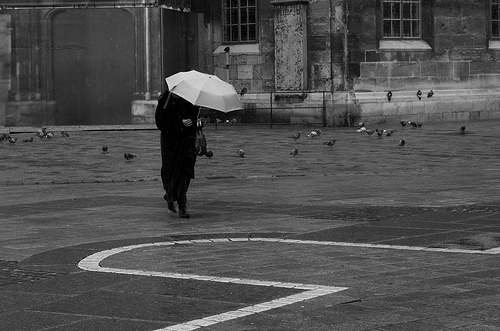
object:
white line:
[77, 235, 500, 330]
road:
[0, 126, 496, 331]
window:
[372, 2, 434, 52]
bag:
[194, 120, 208, 157]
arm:
[154, 95, 182, 131]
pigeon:
[396, 139, 406, 149]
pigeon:
[459, 124, 467, 134]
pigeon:
[236, 147, 245, 158]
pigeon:
[123, 152, 138, 162]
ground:
[4, 127, 496, 326]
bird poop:
[249, 322, 256, 326]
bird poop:
[99, 224, 104, 228]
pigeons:
[364, 129, 375, 135]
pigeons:
[376, 128, 381, 132]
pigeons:
[399, 121, 407, 128]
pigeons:
[306, 129, 321, 141]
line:
[74, 234, 500, 331]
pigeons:
[285, 132, 300, 142]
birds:
[289, 148, 299, 158]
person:
[155, 91, 207, 220]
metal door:
[49, 9, 139, 125]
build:
[2, 0, 499, 130]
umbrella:
[164, 70, 245, 114]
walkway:
[0, 182, 499, 329]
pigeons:
[101, 143, 109, 156]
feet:
[163, 190, 179, 213]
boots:
[163, 188, 177, 214]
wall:
[347, 3, 500, 121]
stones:
[422, 275, 481, 287]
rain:
[12, 222, 479, 312]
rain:
[7, 9, 470, 95]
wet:
[163, 69, 248, 113]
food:
[98, 126, 436, 180]